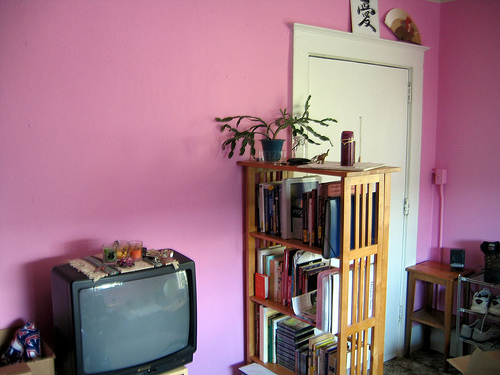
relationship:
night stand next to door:
[397, 247, 483, 371] [281, 15, 443, 371]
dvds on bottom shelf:
[277, 317, 306, 369] [243, 296, 382, 371]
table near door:
[401, 247, 461, 365] [281, 15, 443, 371]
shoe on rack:
[470, 287, 492, 314] [455, 265, 497, 357]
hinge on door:
[408, 80, 412, 102] [309, 54, 411, 368]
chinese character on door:
[356, 0, 371, 37] [298, 17, 422, 357]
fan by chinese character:
[381, 6, 426, 43] [346, 0, 381, 37]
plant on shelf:
[213, 93, 338, 161] [233, 146, 402, 373]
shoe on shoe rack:
[470, 287, 492, 314] [448, 270, 498, 357]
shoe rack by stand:
[460, 270, 492, 345] [405, 245, 463, 360]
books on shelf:
[253, 175, 379, 259] [248, 230, 381, 262]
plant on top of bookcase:
[213, 93, 338, 161] [233, 154, 402, 373]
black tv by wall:
[52, 245, 195, 371] [4, 2, 434, 372]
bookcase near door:
[240, 154, 395, 373] [362, 158, 452, 305]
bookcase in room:
[240, 154, 395, 373] [235, 151, 454, 301]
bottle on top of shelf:
[338, 129, 362, 171] [233, 166, 389, 358]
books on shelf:
[215, 184, 338, 369] [233, 146, 402, 373]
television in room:
[48, 246, 197, 373] [86, 213, 456, 375]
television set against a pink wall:
[90, 246, 197, 373] [91, 163, 220, 276]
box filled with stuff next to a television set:
[167, 249, 299, 359] [94, 272, 224, 375]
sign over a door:
[349, 0, 377, 35] [288, 21, 432, 373]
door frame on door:
[291, 22, 430, 359] [309, 54, 411, 368]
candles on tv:
[78, 234, 168, 269] [45, 247, 198, 374]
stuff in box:
[4, 317, 42, 364] [0, 339, 57, 374]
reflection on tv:
[79, 270, 188, 362] [45, 247, 198, 374]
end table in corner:
[403, 260, 482, 361] [432, 4, 443, 352]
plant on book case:
[213, 93, 338, 161] [236, 132, 392, 372]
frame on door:
[289, 20, 427, 366] [288, 21, 432, 373]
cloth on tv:
[72, 247, 177, 281] [52, 260, 181, 352]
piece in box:
[4, 316, 47, 358] [0, 359, 60, 367]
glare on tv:
[89, 276, 190, 318] [45, 247, 198, 374]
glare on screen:
[89, 276, 190, 318] [78, 268, 191, 372]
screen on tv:
[78, 268, 191, 372] [45, 247, 198, 374]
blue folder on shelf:
[322, 190, 352, 259] [249, 230, 352, 256]